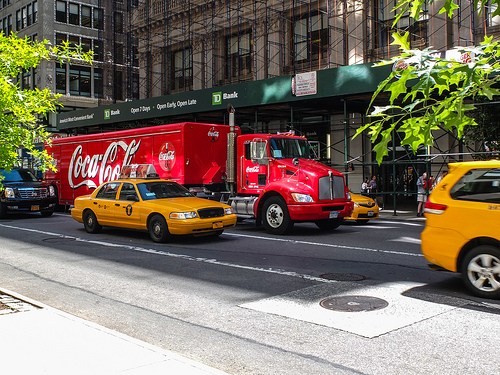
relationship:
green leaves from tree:
[366, 31, 455, 115] [2, 23, 87, 236]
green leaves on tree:
[1, 27, 99, 182] [352, 1, 483, 157]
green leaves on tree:
[351, 2, 499, 165] [2, 26, 100, 217]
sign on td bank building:
[57, 54, 415, 129] [96, 0, 498, 208]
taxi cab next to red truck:
[70, 164, 238, 243] [43, 122, 355, 235]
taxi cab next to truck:
[344, 192, 379, 223] [42, 107, 354, 235]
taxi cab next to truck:
[69, 179, 236, 243] [42, 107, 354, 235]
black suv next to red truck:
[1, 163, 61, 220] [43, 121, 350, 213]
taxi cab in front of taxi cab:
[420, 159, 499, 298] [70, 164, 238, 243]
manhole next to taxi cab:
[318, 289, 396, 312] [413, 150, 484, 302]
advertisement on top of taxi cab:
[117, 161, 157, 180] [66, 178, 236, 248]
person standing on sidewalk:
[416, 172, 431, 215] [372, 203, 427, 224]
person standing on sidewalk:
[416, 171, 430, 217] [0, 148, 258, 373]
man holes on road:
[312, 264, 393, 322] [0, 237, 439, 375]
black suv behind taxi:
[0, 167, 59, 218] [67, 164, 237, 244]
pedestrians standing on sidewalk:
[360, 177, 373, 196] [379, 196, 415, 217]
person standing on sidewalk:
[368, 201, 433, 222] [379, 196, 415, 217]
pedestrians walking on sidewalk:
[358, 163, 379, 207] [353, 190, 448, 247]